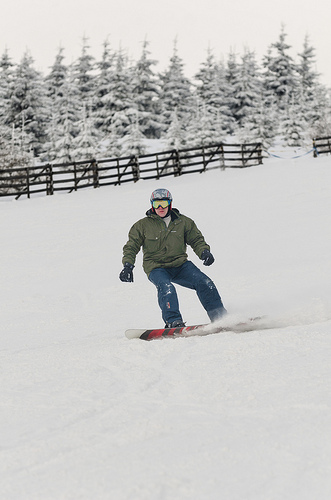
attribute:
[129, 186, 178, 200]
helmet — white, red, silver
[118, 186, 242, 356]
man — going downhill, looking at camera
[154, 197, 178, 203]
goggles — blue, yellow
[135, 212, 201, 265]
jacket — green, hooded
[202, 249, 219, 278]
gloves — black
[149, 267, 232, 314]
pants — blue, snow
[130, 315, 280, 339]
snowboard — red black &white, red white, black, red, red black, white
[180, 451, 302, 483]
snow — white, pure, fresh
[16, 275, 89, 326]
ski slope — snow covered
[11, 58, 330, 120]
trees — snow covered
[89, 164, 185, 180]
fence — wooden, black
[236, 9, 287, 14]
sky — cloudy